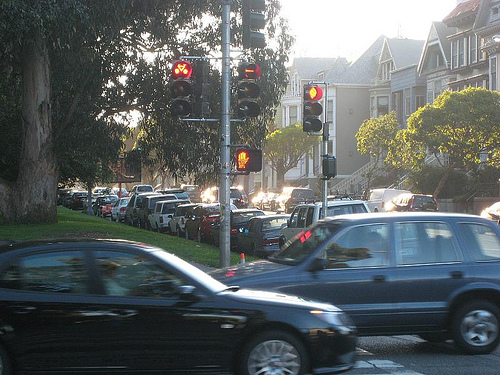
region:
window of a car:
[323, 216, 403, 273]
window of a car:
[385, 225, 455, 268]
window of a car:
[95, 251, 180, 291]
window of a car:
[23, 255, 104, 305]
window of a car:
[326, 201, 376, 225]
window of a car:
[287, 208, 318, 225]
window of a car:
[262, 213, 292, 227]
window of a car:
[243, 215, 270, 233]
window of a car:
[236, 205, 260, 223]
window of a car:
[199, 196, 226, 220]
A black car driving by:
[3, 234, 357, 374]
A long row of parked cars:
[61, 189, 376, 251]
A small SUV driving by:
[195, 210, 499, 353]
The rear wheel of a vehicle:
[448, 293, 498, 350]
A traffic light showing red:
[301, 78, 322, 135]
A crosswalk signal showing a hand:
[237, 148, 263, 169]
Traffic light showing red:
[170, 57, 194, 121]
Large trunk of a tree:
[18, 59, 61, 222]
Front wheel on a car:
[238, 323, 309, 373]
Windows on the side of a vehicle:
[312, 220, 498, 272]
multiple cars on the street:
[23, 192, 478, 359]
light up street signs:
[183, 12, 265, 256]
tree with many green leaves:
[361, 100, 498, 160]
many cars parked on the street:
[107, 195, 260, 239]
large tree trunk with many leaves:
[7, 1, 120, 231]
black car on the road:
[13, 236, 336, 371]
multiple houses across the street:
[288, 61, 486, 175]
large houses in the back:
[286, 44, 488, 176]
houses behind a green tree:
[365, 30, 499, 201]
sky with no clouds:
[293, 2, 454, 55]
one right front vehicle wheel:
[233, 323, 314, 373]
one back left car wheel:
[455, 293, 499, 358]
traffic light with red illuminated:
[299, 77, 329, 137]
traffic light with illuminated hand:
[227, 140, 262, 176]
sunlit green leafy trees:
[351, 82, 497, 194]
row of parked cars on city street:
[66, 171, 353, 254]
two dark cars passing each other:
[7, 182, 488, 369]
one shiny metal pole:
[217, 4, 241, 266]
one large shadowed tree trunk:
[3, 13, 58, 216]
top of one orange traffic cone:
[233, 246, 252, 268]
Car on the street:
[0, 232, 361, 373]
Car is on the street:
[0, 226, 371, 371]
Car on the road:
[0, 227, 370, 373]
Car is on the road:
[0, 229, 371, 373]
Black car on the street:
[2, 232, 365, 372]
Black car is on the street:
[0, 226, 366, 373]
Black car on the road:
[0, 230, 370, 374]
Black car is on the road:
[2, 227, 367, 373]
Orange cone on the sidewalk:
[234, 248, 248, 265]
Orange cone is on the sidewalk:
[235, 249, 250, 269]